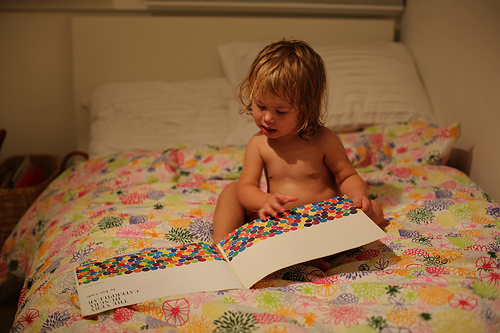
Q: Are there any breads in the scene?
A: Yes, there is a bread.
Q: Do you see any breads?
A: Yes, there is a bread.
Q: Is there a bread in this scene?
A: Yes, there is a bread.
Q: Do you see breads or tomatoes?
A: Yes, there is a bread.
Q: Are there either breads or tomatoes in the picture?
A: Yes, there is a bread.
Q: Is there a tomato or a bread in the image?
A: Yes, there is a bread.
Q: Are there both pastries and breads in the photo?
A: No, there is a bread but no pastries.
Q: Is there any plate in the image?
A: No, there are no plates.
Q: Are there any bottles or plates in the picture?
A: No, there are no plates or bottles.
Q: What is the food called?
A: The food is a bread.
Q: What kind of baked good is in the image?
A: The baked good is a bread.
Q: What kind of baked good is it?
A: The food is a bread.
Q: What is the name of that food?
A: This is a bread.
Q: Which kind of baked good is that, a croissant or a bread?
A: This is a bread.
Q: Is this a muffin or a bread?
A: This is a bread.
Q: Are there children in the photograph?
A: Yes, there is a child.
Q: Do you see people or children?
A: Yes, there is a child.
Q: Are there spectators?
A: No, there are no spectators.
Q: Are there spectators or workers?
A: No, there are no spectators or workers.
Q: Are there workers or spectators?
A: No, there are no spectators or workers.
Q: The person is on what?
A: The child is on the bed.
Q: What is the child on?
A: The child is on the bed.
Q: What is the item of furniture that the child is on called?
A: The piece of furniture is a bed.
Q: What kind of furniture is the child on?
A: The child is on the bed.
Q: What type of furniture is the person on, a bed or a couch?
A: The kid is on a bed.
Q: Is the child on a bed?
A: Yes, the child is on a bed.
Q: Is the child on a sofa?
A: No, the child is on a bed.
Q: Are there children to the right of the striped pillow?
A: Yes, there is a child to the right of the pillow.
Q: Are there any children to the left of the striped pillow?
A: No, the child is to the right of the pillow.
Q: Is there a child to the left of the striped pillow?
A: No, the child is to the right of the pillow.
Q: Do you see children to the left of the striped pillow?
A: No, the child is to the right of the pillow.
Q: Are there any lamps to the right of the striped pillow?
A: No, there is a child to the right of the pillow.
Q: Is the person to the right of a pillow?
A: Yes, the child is to the right of a pillow.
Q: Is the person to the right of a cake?
A: No, the kid is to the right of a pillow.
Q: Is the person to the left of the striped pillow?
A: No, the child is to the right of the pillow.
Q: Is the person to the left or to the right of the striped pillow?
A: The child is to the right of the pillow.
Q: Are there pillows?
A: Yes, there is a pillow.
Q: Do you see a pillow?
A: Yes, there is a pillow.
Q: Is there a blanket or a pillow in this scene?
A: Yes, there is a pillow.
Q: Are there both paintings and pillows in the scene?
A: No, there is a pillow but no paintings.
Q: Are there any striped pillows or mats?
A: Yes, there is a striped pillow.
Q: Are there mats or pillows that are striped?
A: Yes, the pillow is striped.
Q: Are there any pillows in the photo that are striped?
A: Yes, there is a striped pillow.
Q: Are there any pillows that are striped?
A: Yes, there is a pillow that is striped.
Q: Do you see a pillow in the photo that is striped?
A: Yes, there is a pillow that is striped.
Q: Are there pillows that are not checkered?
A: Yes, there is a striped pillow.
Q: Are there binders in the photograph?
A: No, there are no binders.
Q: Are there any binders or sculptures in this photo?
A: No, there are no binders or sculptures.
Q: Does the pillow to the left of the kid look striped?
A: Yes, the pillow is striped.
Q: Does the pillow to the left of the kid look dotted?
A: No, the pillow is striped.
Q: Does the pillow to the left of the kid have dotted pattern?
A: No, the pillow is striped.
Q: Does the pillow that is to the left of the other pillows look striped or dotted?
A: The pillow is striped.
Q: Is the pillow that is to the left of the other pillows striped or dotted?
A: The pillow is striped.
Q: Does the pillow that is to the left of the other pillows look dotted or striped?
A: The pillow is striped.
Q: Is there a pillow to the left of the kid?
A: Yes, there is a pillow to the left of the kid.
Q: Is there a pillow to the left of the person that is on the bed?
A: Yes, there is a pillow to the left of the kid.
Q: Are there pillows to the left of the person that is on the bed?
A: Yes, there is a pillow to the left of the kid.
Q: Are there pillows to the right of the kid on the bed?
A: No, the pillow is to the left of the child.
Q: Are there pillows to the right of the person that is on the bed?
A: No, the pillow is to the left of the child.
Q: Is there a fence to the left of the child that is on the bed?
A: No, there is a pillow to the left of the child.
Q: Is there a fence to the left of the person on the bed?
A: No, there is a pillow to the left of the child.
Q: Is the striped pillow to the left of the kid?
A: Yes, the pillow is to the left of the kid.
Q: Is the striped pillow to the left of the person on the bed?
A: Yes, the pillow is to the left of the kid.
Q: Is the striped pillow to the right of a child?
A: No, the pillow is to the left of a child.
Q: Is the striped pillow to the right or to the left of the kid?
A: The pillow is to the left of the kid.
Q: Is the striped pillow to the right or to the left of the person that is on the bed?
A: The pillow is to the left of the kid.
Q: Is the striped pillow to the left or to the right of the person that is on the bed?
A: The pillow is to the left of the kid.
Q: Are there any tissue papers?
A: No, there are no tissue papers.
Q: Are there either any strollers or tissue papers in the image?
A: No, there are no tissue papers or strollers.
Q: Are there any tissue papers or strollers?
A: No, there are no tissue papers or strollers.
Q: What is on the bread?
A: The flower is on the bread.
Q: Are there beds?
A: Yes, there is a bed.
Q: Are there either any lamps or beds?
A: Yes, there is a bed.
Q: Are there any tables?
A: No, there are no tables.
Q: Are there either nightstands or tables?
A: No, there are no tables or nightstands.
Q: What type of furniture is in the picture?
A: The furniture is a bed.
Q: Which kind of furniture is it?
A: The piece of furniture is a bed.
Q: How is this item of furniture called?
A: This is a bed.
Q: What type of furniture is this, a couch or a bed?
A: This is a bed.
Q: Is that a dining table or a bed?
A: That is a bed.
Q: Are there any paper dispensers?
A: No, there are no paper dispensers.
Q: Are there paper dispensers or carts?
A: No, there are no paper dispensers or carts.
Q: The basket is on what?
A: The basket is on the bed.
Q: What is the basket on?
A: The basket is on the bed.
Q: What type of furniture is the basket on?
A: The basket is on the bed.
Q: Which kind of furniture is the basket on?
A: The basket is on the bed.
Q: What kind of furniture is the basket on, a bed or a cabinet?
A: The basket is on a bed.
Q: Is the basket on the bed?
A: Yes, the basket is on the bed.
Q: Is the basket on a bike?
A: No, the basket is on the bed.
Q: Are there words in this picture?
A: Yes, there are words.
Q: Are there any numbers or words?
A: Yes, there are words.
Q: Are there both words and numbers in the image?
A: No, there are words but no numbers.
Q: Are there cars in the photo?
A: No, there are no cars.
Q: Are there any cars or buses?
A: No, there are no cars or buses.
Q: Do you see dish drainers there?
A: No, there are no dish drainers.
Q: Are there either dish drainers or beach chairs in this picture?
A: No, there are no dish drainers or beach chairs.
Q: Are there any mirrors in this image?
A: No, there are no mirrors.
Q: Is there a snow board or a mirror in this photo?
A: No, there are no mirrors or snowboards.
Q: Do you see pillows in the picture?
A: Yes, there are pillows.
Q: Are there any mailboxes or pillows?
A: Yes, there are pillows.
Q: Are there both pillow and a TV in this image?
A: No, there are pillows but no televisions.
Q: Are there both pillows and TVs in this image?
A: No, there are pillows but no televisions.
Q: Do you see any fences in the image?
A: No, there are no fences.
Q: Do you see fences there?
A: No, there are no fences.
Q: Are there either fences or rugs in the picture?
A: No, there are no fences or rugs.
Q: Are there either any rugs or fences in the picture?
A: No, there are no fences or rugs.